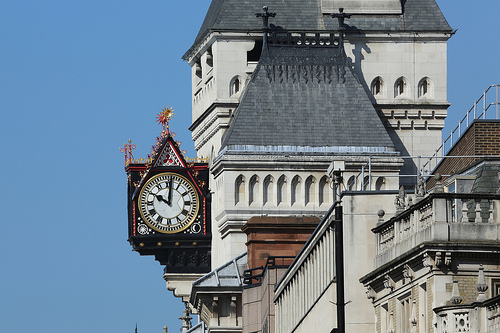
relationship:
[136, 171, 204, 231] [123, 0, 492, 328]
clock on building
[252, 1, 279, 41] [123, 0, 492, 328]
cross on building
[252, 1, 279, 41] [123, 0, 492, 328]
cross on top of building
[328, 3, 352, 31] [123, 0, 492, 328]
cross on top of building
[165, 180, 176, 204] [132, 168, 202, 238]
arms on clock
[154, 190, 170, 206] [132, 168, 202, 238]
hand on clock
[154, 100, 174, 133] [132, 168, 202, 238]
decorations hanging on top of clock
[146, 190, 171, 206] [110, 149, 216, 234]
hand on clock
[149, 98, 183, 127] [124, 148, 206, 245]
item on clock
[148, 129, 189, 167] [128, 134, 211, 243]
triangle on clock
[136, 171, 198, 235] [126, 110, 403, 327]
clock extending from building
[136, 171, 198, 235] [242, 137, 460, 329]
clock on building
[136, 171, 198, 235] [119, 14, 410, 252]
clock at the top of the building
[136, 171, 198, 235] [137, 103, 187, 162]
clock with a top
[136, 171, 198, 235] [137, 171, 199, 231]
clock with a ring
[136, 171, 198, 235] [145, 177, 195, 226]
clock with numbers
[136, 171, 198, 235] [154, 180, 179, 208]
clock with arms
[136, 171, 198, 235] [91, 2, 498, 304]
clock on building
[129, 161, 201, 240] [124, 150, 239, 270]
roman numerals on clock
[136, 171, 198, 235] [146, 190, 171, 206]
clock has a hand